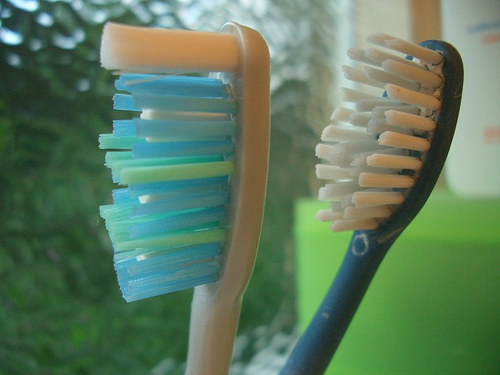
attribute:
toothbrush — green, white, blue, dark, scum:
[91, 49, 247, 309]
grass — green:
[56, 301, 97, 316]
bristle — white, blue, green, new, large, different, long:
[342, 71, 425, 181]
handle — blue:
[283, 273, 426, 343]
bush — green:
[15, 83, 98, 173]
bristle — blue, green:
[143, 64, 232, 246]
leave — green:
[62, 24, 105, 66]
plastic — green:
[409, 220, 483, 296]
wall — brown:
[382, 9, 394, 26]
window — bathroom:
[290, 9, 321, 66]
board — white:
[467, 26, 472, 43]